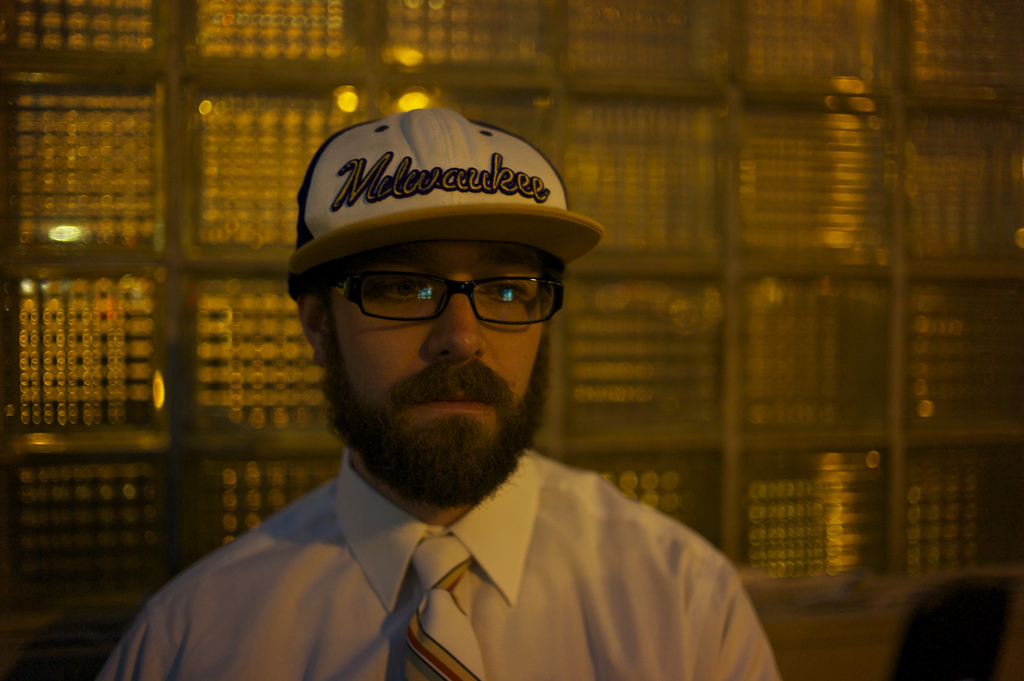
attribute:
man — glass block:
[67, 52, 823, 675]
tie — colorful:
[410, 517, 491, 676]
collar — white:
[316, 446, 585, 601]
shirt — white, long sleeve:
[81, 456, 829, 676]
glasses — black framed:
[318, 257, 576, 330]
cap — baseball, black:
[325, 153, 566, 217]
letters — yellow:
[336, 161, 553, 205]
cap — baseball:
[288, 113, 615, 282]